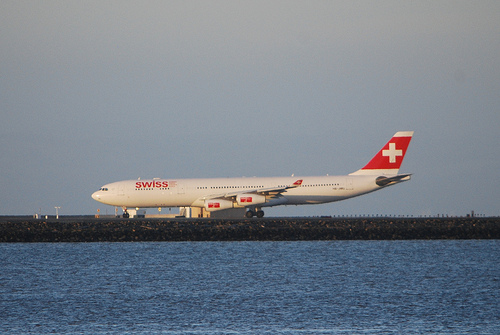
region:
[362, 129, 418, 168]
a white cross on a plane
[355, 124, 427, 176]
a white cross on a red background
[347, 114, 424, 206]
the tail section of a passenger plane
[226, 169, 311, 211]
the left wing of a plane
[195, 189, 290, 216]
the left engines of a plane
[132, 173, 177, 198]
Swiss written on a plane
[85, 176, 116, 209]
the cockpit of a plane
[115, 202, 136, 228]
the front wheels of a plane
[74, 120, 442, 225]
a plane preparing to taxi on runway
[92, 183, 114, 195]
part on a plane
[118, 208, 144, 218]
part on a plane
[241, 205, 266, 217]
part on a plane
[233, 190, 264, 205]
part on a plane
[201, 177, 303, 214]
part on a plane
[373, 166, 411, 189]
part on a plane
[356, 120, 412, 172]
part on a plane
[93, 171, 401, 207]
part on a plane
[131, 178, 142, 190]
red letter on plane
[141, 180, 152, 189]
red letter on plane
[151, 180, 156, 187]
red letter on plane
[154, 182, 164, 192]
red letter on plane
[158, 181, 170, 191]
red letter on plane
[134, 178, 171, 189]
red letters on plane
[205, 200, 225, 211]
red decal on plane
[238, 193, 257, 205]
red decal on plane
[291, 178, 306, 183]
red decal on plane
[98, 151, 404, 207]
white airliner on tarmac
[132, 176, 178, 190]
swiss written on side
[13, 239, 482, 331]
body of water in foreground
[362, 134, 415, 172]
red tail of plane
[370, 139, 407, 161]
whtie cross on red tail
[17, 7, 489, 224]
blue sky above plane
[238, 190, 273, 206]
large engine under wing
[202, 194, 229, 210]
large engine under wing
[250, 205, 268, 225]
landing gear under plane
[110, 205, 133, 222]
landing gear under plane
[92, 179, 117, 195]
part on a plane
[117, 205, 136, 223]
part on a plane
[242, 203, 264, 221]
part on a plane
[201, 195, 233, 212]
part on a plane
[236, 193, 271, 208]
part on a plane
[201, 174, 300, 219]
part on a plane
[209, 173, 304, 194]
part on a plane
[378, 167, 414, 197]
part on a plane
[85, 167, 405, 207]
part on a plane